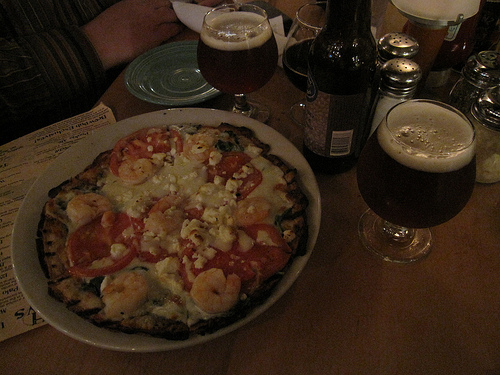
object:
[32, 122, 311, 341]
dinner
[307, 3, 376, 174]
liquid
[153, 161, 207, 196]
cheese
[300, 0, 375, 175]
bottle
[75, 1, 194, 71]
hand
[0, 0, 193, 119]
person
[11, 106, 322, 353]
plate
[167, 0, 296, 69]
napkin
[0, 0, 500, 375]
table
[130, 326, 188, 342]
bread crust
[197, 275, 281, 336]
bread crust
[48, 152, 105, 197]
bread crust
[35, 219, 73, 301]
bread crust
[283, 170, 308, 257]
bread crust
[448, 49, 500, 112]
shaker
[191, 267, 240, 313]
shrimp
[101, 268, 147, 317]
shrimp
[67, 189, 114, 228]
shrimp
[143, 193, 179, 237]
shrimp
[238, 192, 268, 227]
shrimp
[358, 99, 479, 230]
wine glass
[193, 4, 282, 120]
wine glass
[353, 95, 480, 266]
glass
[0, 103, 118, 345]
paper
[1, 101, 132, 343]
menu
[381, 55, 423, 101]
salt shaker